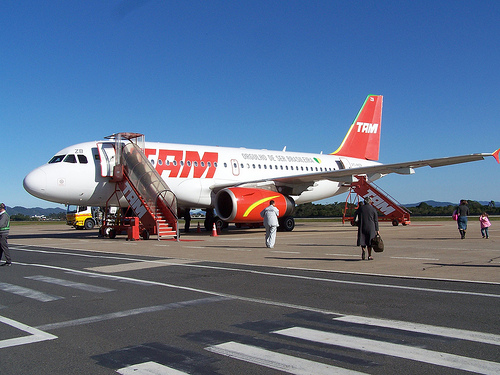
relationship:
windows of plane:
[41, 143, 105, 173] [65, 97, 332, 238]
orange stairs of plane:
[116, 144, 179, 239] [16, 87, 498, 242]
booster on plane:
[213, 183, 297, 230] [16, 87, 498, 242]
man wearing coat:
[345, 192, 387, 250] [360, 204, 373, 246]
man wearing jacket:
[260, 200, 277, 250] [260, 205, 278, 228]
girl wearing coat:
[479, 213, 492, 240] [479, 217, 491, 228]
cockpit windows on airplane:
[47, 155, 87, 165] [22, 94, 498, 242]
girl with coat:
[469, 199, 499, 237] [480, 215, 492, 225]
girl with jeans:
[469, 199, 499, 237] [477, 228, 493, 238]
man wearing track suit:
[260, 200, 279, 248] [265, 206, 273, 233]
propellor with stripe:
[211, 182, 296, 224] [242, 193, 277, 215]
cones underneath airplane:
[191, 214, 223, 236] [9, 68, 498, 258]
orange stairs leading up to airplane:
[116, 144, 179, 239] [29, 134, 432, 212]